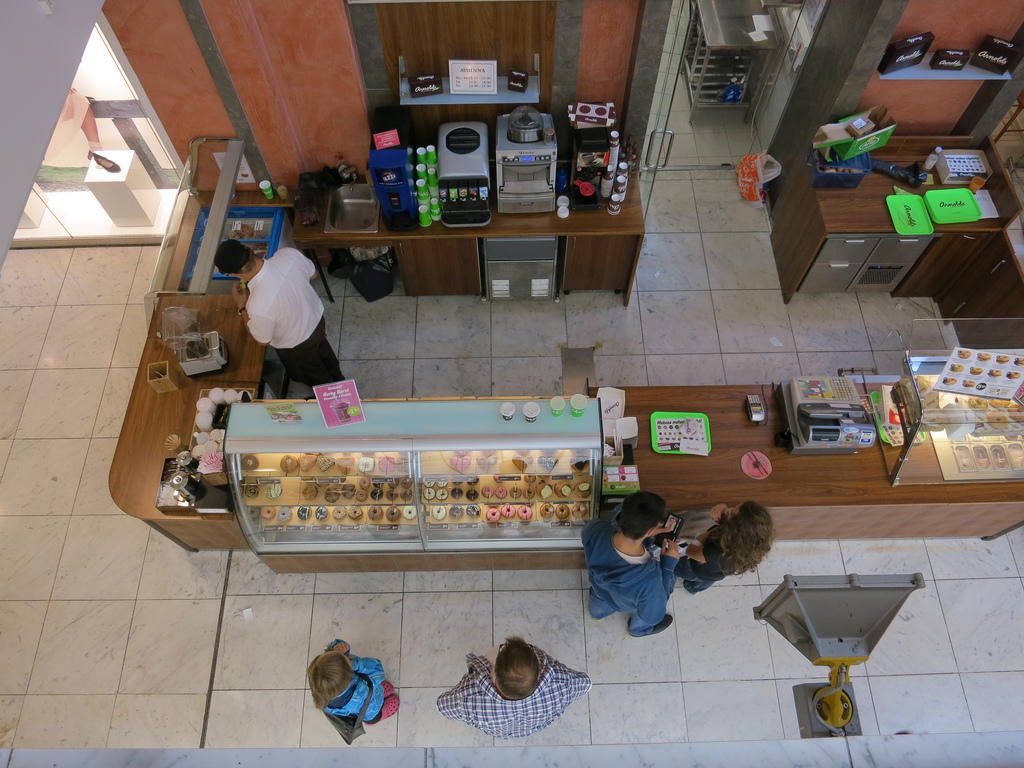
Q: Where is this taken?
A: In a bakery.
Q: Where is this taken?
A: In a bakery.